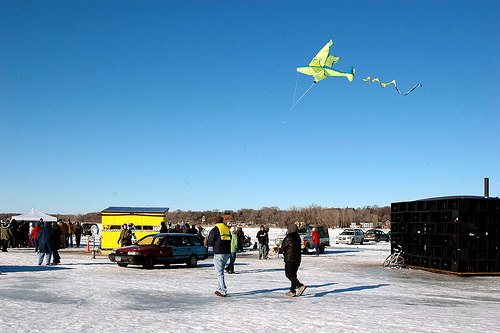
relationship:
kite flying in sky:
[296, 39, 422, 97] [349, 11, 491, 71]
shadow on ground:
[304, 280, 391, 299] [0, 227, 497, 331]